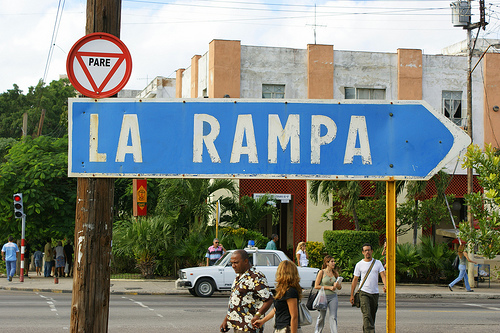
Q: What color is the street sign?
A: Blue and white.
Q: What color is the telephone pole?
A: Brown.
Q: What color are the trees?
A: Green.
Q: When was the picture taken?
A: Daytime.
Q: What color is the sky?
A: Blue.